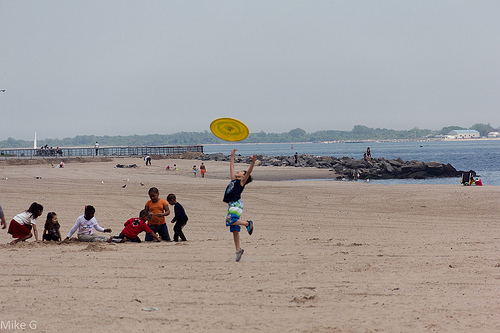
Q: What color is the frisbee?
A: Yellow.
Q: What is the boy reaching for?
A: Frisbee.